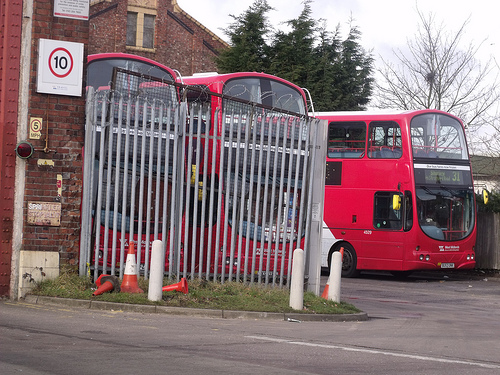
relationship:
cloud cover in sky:
[391, 36, 483, 79] [178, 0, 496, 155]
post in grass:
[328, 251, 343, 303] [32, 268, 362, 317]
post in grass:
[288, 249, 305, 310] [32, 268, 362, 317]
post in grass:
[148, 240, 166, 302] [32, 268, 362, 317]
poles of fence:
[83, 87, 329, 292] [81, 84, 329, 294]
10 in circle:
[53, 55, 68, 69] [47, 47, 74, 76]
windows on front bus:
[406, 111, 476, 243] [315, 111, 481, 276]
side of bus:
[316, 111, 413, 267] [315, 111, 481, 276]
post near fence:
[330, 252, 340, 301] [81, 84, 329, 294]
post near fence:
[288, 249, 305, 310] [81, 84, 329, 294]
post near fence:
[146, 236, 164, 302] [81, 84, 329, 294]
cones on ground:
[92, 241, 188, 299] [2, 273, 496, 370]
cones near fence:
[92, 241, 188, 299] [81, 84, 329, 294]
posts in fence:
[79, 85, 102, 288] [81, 84, 329, 294]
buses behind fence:
[89, 56, 323, 295] [74, 80, 323, 308]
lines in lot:
[246, 325, 498, 372] [5, 260, 496, 369]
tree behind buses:
[211, 1, 380, 116] [84, 51, 484, 301]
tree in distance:
[356, 19, 498, 153] [2, 0, 497, 175]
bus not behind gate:
[302, 96, 484, 280] [90, 83, 333, 303]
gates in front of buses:
[72, 80, 328, 308] [78, 44, 321, 301]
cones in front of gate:
[87, 241, 192, 315] [74, 81, 327, 294]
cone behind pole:
[322, 235, 356, 303] [312, 115, 329, 297]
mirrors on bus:
[378, 177, 498, 222] [315, 111, 481, 276]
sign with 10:
[35, 37, 85, 98] [52, 55, 73, 75]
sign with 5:
[23, 112, 53, 151] [30, 118, 42, 136]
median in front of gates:
[34, 242, 367, 329] [76, 73, 347, 303]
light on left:
[14, 140, 34, 159] [4, 2, 257, 373]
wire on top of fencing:
[89, 64, 323, 127] [71, 68, 331, 299]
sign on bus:
[418, 165, 467, 187] [296, 105, 478, 285]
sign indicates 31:
[418, 165, 467, 187] [448, 166, 467, 186]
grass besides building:
[28, 269, 353, 331] [3, 5, 261, 314]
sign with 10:
[31, 35, 87, 101] [55, 54, 70, 74]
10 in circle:
[55, 54, 70, 74] [44, 44, 79, 82]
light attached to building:
[12, 137, 37, 164] [4, 3, 489, 373]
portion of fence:
[472, 193, 499, 275] [469, 190, 499, 278]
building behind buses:
[87, 1, 243, 70] [81, 52, 480, 277]